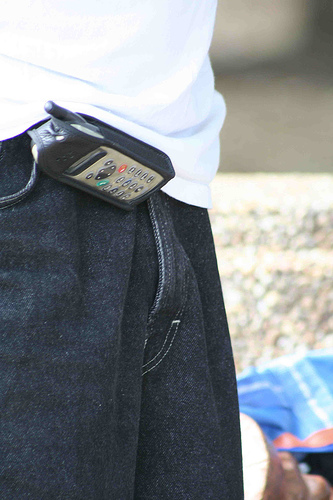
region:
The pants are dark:
[24, 266, 141, 401]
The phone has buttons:
[41, 100, 202, 221]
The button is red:
[113, 160, 130, 175]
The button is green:
[93, 178, 110, 189]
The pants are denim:
[81, 403, 206, 494]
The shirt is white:
[49, 40, 192, 151]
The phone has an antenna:
[37, 96, 92, 141]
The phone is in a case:
[35, 106, 198, 241]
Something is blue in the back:
[255, 365, 321, 442]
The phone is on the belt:
[8, 81, 154, 208]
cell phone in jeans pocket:
[37, 127, 151, 197]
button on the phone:
[118, 165, 127, 174]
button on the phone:
[95, 177, 106, 186]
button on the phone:
[149, 175, 157, 184]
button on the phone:
[82, 169, 95, 178]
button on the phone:
[100, 156, 112, 167]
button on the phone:
[133, 186, 142, 193]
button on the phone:
[110, 184, 115, 193]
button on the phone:
[104, 160, 113, 166]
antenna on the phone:
[31, 96, 79, 128]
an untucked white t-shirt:
[2, 1, 222, 206]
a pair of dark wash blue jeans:
[7, 140, 243, 499]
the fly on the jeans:
[142, 200, 182, 373]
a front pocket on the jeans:
[0, 139, 39, 210]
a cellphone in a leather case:
[31, 101, 174, 211]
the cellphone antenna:
[44, 99, 79, 120]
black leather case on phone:
[32, 121, 173, 213]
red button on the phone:
[119, 162, 127, 173]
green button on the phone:
[95, 179, 108, 185]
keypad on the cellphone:
[81, 159, 155, 201]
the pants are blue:
[172, 440, 199, 471]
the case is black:
[121, 134, 138, 149]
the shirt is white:
[134, 19, 164, 34]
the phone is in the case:
[78, 124, 100, 144]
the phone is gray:
[107, 149, 118, 158]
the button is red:
[118, 166, 125, 174]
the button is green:
[97, 180, 109, 186]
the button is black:
[99, 169, 113, 178]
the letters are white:
[115, 176, 124, 184]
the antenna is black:
[45, 101, 61, 115]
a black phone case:
[25, 98, 173, 212]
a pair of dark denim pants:
[0, 127, 244, 499]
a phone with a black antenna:
[24, 99, 174, 212]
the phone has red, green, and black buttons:
[26, 100, 174, 212]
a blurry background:
[206, 0, 332, 498]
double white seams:
[142, 296, 185, 376]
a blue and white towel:
[237, 352, 332, 466]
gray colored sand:
[210, 205, 329, 379]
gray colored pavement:
[209, 0, 329, 172]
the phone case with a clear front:
[28, 116, 173, 211]